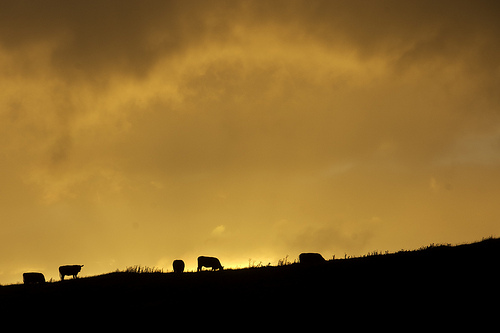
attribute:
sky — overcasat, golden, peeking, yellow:
[3, 4, 483, 259]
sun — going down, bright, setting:
[204, 218, 285, 271]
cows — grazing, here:
[46, 261, 96, 283]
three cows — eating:
[50, 242, 335, 289]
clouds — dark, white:
[73, 54, 434, 185]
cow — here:
[57, 261, 89, 281]